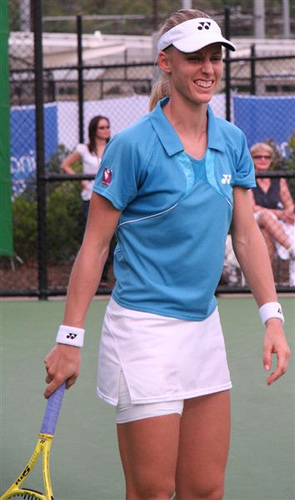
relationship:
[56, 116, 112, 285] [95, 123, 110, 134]
person wearing sunglasses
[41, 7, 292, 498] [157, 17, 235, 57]
woman wearing cap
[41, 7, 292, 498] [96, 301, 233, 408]
woman wearing skirt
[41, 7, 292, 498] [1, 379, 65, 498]
woman holding tennis racket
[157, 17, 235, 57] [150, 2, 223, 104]
cap on head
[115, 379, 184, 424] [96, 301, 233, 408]
shorts under skirt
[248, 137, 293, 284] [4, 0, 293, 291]
spectator behind fence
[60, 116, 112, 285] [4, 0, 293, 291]
person behind fence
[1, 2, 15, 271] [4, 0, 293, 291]
tarp on fence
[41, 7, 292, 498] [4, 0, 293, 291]
woman in front of fence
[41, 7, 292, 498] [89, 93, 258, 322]
woman wearing shirt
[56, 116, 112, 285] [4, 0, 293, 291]
person behind fence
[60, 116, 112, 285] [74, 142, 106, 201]
person wearing white shirt